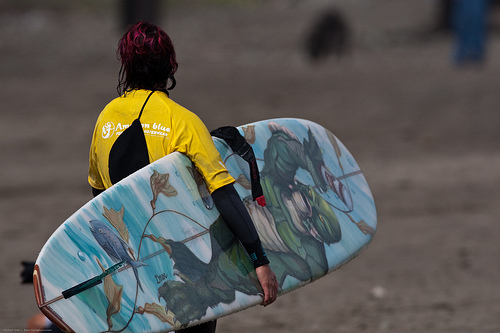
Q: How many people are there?
A: One.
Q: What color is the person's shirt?
A: Yellow.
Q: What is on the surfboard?
A: Lizard.